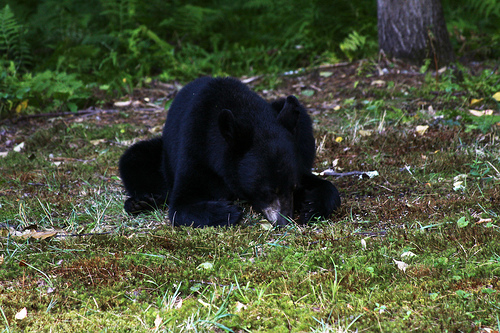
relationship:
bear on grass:
[117, 76, 341, 227] [21, 27, 499, 312]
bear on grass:
[117, 76, 341, 227] [22, 19, 490, 292]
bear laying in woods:
[117, 76, 341, 227] [3, 1, 473, 319]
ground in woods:
[2, 117, 481, 323] [3, 1, 473, 319]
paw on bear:
[121, 190, 163, 215] [117, 76, 341, 227]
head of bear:
[213, 93, 305, 238] [117, 76, 341, 227]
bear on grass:
[117, 76, 341, 227] [2, 62, 491, 329]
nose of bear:
[276, 212, 294, 232] [103, 57, 363, 259]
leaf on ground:
[9, 224, 59, 241] [9, 232, 491, 324]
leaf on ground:
[392, 250, 417, 273] [9, 232, 491, 324]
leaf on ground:
[449, 170, 471, 194] [9, 232, 491, 324]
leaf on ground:
[84, 132, 108, 148] [9, 232, 491, 324]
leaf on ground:
[369, 76, 390, 89] [9, 232, 491, 324]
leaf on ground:
[453, 173, 468, 191] [0, 59, 499, 331]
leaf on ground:
[392, 254, 413, 275] [0, 59, 499, 331]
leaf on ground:
[392, 250, 417, 273] [0, 59, 499, 331]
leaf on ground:
[10, 304, 31, 322] [0, 59, 499, 331]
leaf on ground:
[5, 226, 59, 242] [0, 59, 499, 331]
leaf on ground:
[228, 296, 250, 325] [0, 59, 499, 331]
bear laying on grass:
[117, 76, 341, 227] [7, 220, 494, 328]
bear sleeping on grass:
[117, 76, 341, 227] [8, 214, 495, 321]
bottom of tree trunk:
[371, 29, 461, 66] [379, 1, 454, 65]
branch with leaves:
[1, 211, 106, 258] [11, 225, 61, 248]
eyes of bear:
[250, 175, 302, 193] [117, 76, 341, 227]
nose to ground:
[255, 212, 298, 234] [359, 180, 471, 295]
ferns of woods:
[1, 3, 498, 118] [4, 10, 498, 331]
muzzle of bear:
[251, 177, 326, 240] [101, 45, 356, 235]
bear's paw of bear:
[170, 201, 245, 231] [117, 76, 341, 227]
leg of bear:
[117, 136, 165, 218] [117, 76, 341, 227]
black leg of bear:
[277, 95, 319, 168] [117, 76, 341, 227]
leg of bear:
[119, 140, 165, 192] [117, 76, 341, 227]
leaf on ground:
[5, 226, 59, 242] [2, 197, 490, 325]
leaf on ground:
[392, 250, 417, 273] [2, 197, 490, 325]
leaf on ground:
[14, 304, 31, 321] [2, 197, 490, 325]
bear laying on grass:
[117, 76, 341, 227] [2, 62, 491, 329]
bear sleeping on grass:
[89, 84, 371, 249] [42, 124, 459, 290]